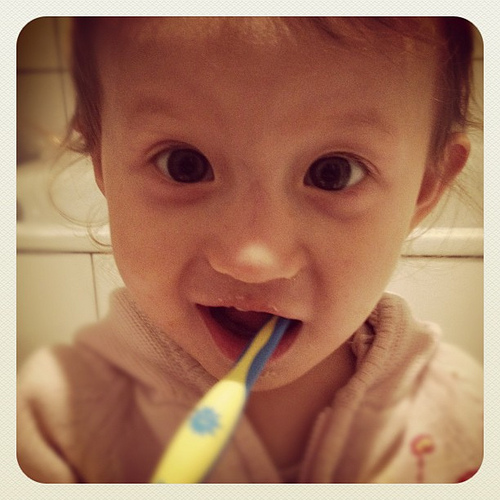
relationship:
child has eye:
[55, 72, 443, 397] [143, 141, 248, 206]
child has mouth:
[55, 72, 443, 397] [164, 272, 350, 382]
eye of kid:
[143, 141, 248, 206] [117, 48, 443, 388]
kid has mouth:
[117, 48, 443, 388] [164, 272, 350, 382]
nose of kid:
[165, 231, 317, 310] [117, 48, 443, 388]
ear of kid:
[343, 112, 490, 259] [117, 48, 443, 388]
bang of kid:
[34, 52, 141, 173] [117, 48, 443, 388]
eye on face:
[143, 141, 248, 206] [64, 57, 455, 403]